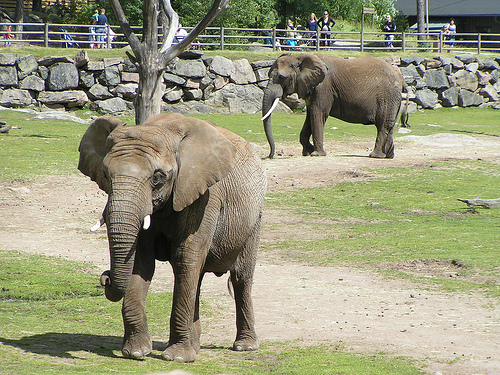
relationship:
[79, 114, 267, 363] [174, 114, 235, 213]
elephant has ear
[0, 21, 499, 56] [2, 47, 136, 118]
fence over rocks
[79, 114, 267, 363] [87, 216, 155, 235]
elephant has tusks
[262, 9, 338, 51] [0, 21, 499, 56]
people behind fence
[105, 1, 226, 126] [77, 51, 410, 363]
tree near elephants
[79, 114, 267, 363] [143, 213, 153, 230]
elephant has horn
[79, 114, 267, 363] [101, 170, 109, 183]
elephant has eye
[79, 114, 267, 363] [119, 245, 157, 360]
elephant has leg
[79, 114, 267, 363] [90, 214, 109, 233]
elephant has tusk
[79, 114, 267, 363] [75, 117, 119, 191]
elephant has ear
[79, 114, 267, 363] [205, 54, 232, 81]
elephant near stone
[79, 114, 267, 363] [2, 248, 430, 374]
elephant in grass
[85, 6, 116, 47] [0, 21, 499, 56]
spectators along fence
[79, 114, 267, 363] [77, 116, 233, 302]
elephant has head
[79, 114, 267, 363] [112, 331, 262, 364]
elephant has feet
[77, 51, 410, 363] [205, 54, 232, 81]
elephants near stone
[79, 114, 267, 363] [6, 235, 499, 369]
elephant in sand